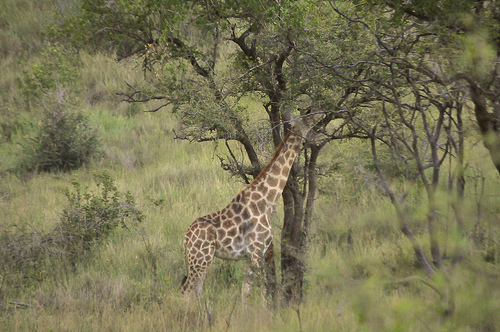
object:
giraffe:
[180, 101, 333, 308]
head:
[297, 102, 332, 128]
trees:
[59, 0, 499, 312]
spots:
[216, 216, 264, 248]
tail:
[178, 238, 190, 291]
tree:
[315, 0, 499, 317]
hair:
[244, 126, 295, 186]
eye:
[304, 106, 314, 115]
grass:
[0, 0, 499, 331]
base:
[255, 168, 317, 304]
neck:
[254, 124, 306, 205]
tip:
[177, 274, 189, 289]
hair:
[179, 275, 189, 287]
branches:
[76, 0, 164, 62]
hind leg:
[177, 251, 212, 297]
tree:
[328, 0, 499, 172]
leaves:
[63, 3, 123, 46]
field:
[0, 0, 499, 331]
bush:
[0, 81, 107, 175]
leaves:
[20, 57, 66, 79]